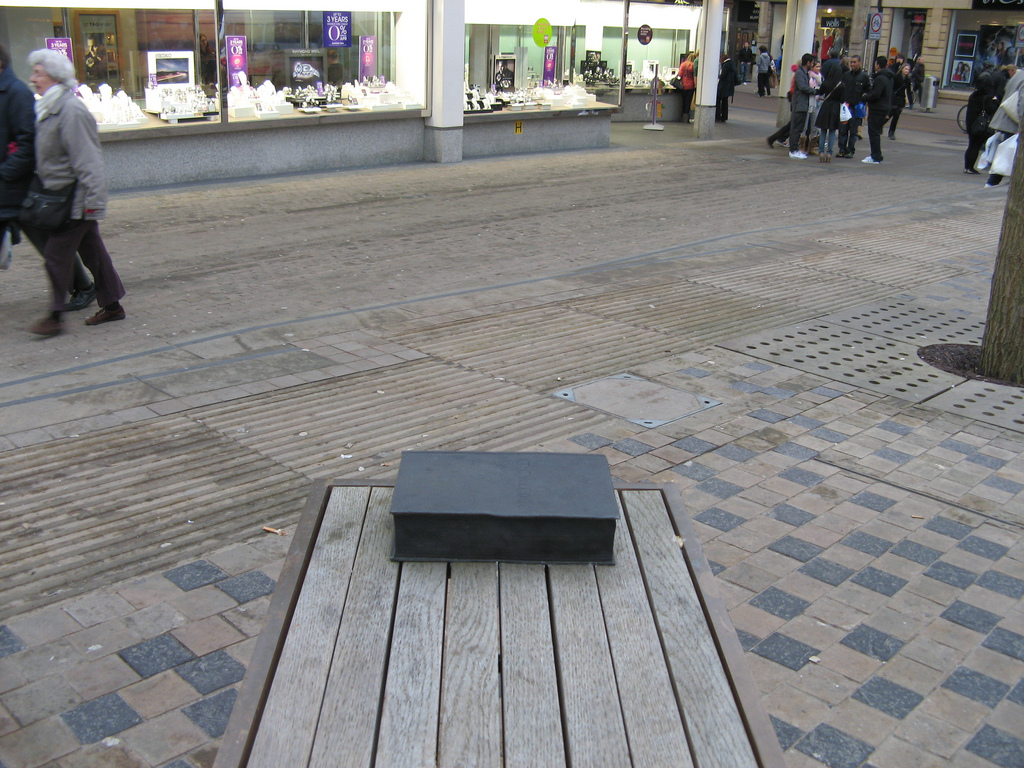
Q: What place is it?
A: It is a sidewalk.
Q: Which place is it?
A: It is a sidewalk.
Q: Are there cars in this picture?
A: No, there are no cars.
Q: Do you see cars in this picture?
A: No, there are no cars.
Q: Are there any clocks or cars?
A: No, there are no cars or clocks.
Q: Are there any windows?
A: Yes, there is a window.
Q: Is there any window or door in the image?
A: Yes, there is a window.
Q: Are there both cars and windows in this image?
A: No, there is a window but no cars.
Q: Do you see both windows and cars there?
A: No, there is a window but no cars.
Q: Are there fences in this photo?
A: No, there are no fences.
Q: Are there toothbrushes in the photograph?
A: No, there are no toothbrushes.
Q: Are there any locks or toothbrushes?
A: No, there are no toothbrushes or locks.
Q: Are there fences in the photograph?
A: No, there are no fences.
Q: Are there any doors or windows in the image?
A: Yes, there is a window.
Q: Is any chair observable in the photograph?
A: No, there are no chairs.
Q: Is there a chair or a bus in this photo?
A: No, there are no chairs or buses.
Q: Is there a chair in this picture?
A: No, there are no chairs.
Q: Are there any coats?
A: Yes, there is a coat.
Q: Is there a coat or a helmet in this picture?
A: Yes, there is a coat.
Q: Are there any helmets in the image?
A: No, there are no helmets.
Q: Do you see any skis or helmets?
A: No, there are no helmets or skis.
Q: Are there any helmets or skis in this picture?
A: No, there are no helmets or skis.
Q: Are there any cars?
A: No, there are no cars.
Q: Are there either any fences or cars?
A: No, there are no cars or fences.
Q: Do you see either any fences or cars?
A: No, there are no cars or fences.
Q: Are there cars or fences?
A: No, there are no cars or fences.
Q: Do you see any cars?
A: No, there are no cars.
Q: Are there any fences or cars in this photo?
A: No, there are no cars or fences.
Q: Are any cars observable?
A: No, there are no cars.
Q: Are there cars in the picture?
A: No, there are no cars.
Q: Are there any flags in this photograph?
A: No, there are no flags.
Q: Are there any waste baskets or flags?
A: No, there are no flags or waste baskets.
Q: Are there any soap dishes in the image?
A: No, there are no soap dishes.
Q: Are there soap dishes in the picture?
A: No, there are no soap dishes.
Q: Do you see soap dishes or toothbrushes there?
A: No, there are no soap dishes or toothbrushes.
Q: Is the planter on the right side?
A: Yes, the planter is on the right of the image.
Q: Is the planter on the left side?
A: No, the planter is on the right of the image.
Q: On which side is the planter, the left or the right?
A: The planter is on the right of the image.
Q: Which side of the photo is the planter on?
A: The planter is on the right of the image.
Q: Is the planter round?
A: Yes, the planter is round.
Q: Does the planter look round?
A: Yes, the planter is round.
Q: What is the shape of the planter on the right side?
A: The planter is round.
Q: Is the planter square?
A: No, the planter is round.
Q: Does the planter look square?
A: No, the planter is round.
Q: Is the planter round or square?
A: The planter is round.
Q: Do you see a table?
A: Yes, there is a table.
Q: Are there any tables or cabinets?
A: Yes, there is a table.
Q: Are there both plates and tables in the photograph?
A: No, there is a table but no plates.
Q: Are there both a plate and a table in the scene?
A: No, there is a table but no plates.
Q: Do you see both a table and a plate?
A: No, there is a table but no plates.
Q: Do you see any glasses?
A: No, there are no glasses.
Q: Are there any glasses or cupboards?
A: No, there are no glasses or cupboards.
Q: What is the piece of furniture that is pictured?
A: The piece of furniture is a table.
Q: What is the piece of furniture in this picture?
A: The piece of furniture is a table.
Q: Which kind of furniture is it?
A: The piece of furniture is a table.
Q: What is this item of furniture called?
A: This is a table.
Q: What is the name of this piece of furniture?
A: This is a table.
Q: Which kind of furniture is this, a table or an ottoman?
A: This is a table.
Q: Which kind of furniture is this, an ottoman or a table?
A: This is a table.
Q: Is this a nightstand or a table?
A: This is a table.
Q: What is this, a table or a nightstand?
A: This is a table.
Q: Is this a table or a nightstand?
A: This is a table.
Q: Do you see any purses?
A: Yes, there is a purse.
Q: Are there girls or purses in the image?
A: Yes, there is a purse.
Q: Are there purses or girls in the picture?
A: Yes, there is a purse.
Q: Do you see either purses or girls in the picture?
A: Yes, there is a purse.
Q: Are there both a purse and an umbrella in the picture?
A: No, there is a purse but no umbrellas.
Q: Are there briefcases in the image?
A: No, there are no briefcases.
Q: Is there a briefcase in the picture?
A: No, there are no briefcases.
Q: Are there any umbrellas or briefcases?
A: No, there are no briefcases or umbrellas.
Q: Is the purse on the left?
A: Yes, the purse is on the left of the image.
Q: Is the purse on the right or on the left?
A: The purse is on the left of the image.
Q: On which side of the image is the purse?
A: The purse is on the left of the image.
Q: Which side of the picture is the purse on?
A: The purse is on the left of the image.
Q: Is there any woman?
A: Yes, there is a woman.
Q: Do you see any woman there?
A: Yes, there is a woman.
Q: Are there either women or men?
A: Yes, there is a woman.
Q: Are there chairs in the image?
A: No, there are no chairs.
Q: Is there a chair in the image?
A: No, there are no chairs.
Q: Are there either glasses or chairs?
A: No, there are no chairs or glasses.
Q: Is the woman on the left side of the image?
A: Yes, the woman is on the left of the image.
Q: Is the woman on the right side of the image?
A: No, the woman is on the left of the image.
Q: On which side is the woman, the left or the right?
A: The woman is on the left of the image.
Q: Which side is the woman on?
A: The woman is on the left of the image.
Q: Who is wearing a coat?
A: The woman is wearing a coat.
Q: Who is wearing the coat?
A: The woman is wearing a coat.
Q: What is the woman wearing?
A: The woman is wearing a coat.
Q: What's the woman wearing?
A: The woman is wearing a coat.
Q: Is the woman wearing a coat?
A: Yes, the woman is wearing a coat.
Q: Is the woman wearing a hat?
A: No, the woman is wearing a coat.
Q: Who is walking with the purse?
A: The woman is walking with the purse.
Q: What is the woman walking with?
A: The woman is walking with a purse.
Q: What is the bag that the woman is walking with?
A: The bag is a purse.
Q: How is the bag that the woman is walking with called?
A: The bag is a purse.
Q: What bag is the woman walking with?
A: The woman is walking with a purse.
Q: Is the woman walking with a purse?
A: Yes, the woman is walking with a purse.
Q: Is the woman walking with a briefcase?
A: No, the woman is walking with a purse.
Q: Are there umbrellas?
A: No, there are no umbrellas.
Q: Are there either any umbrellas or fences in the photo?
A: No, there are no umbrellas or fences.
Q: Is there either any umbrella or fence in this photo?
A: No, there are no umbrellas or fences.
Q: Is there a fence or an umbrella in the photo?
A: No, there are no umbrellas or fences.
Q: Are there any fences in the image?
A: No, there are no fences.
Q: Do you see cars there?
A: No, there are no cars.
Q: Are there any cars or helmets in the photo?
A: No, there are no cars or helmets.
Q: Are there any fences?
A: No, there are no fences.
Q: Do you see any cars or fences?
A: No, there are no fences or cars.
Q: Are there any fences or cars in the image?
A: No, there are no fences or cars.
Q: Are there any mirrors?
A: No, there are no mirrors.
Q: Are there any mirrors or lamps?
A: No, there are no mirrors or lamps.